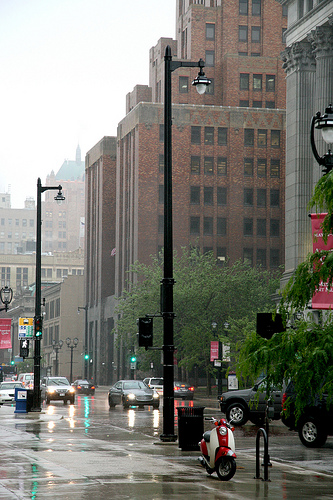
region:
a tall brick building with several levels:
[85, 0, 285, 383]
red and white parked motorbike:
[196, 414, 237, 479]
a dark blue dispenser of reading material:
[13, 386, 26, 414]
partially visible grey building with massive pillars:
[283, 1, 331, 328]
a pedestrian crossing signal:
[19, 337, 30, 357]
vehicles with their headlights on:
[30, 370, 193, 408]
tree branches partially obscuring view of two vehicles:
[217, 304, 331, 446]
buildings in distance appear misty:
[0, 142, 84, 286]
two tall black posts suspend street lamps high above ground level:
[29, 44, 211, 440]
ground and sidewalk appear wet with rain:
[0, 386, 330, 498]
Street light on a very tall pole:
[30, 174, 69, 418]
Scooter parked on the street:
[193, 413, 241, 483]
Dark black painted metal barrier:
[252, 425, 273, 484]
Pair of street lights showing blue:
[81, 352, 140, 365]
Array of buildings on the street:
[0, 0, 332, 405]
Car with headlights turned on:
[105, 375, 161, 409]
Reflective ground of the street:
[0, 393, 331, 498]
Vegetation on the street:
[106, 242, 332, 444]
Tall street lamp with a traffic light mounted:
[136, 42, 212, 448]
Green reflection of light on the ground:
[79, 392, 94, 448]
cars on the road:
[3, 361, 332, 448]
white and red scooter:
[193, 410, 244, 480]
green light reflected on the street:
[79, 394, 94, 435]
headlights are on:
[121, 387, 161, 403]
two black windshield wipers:
[48, 376, 70, 387]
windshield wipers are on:
[49, 377, 70, 386]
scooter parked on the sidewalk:
[191, 411, 246, 480]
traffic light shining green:
[78, 350, 92, 366]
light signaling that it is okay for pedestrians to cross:
[19, 335, 30, 348]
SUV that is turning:
[212, 368, 301, 427]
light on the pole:
[155, 40, 211, 91]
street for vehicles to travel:
[146, 381, 306, 427]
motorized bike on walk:
[187, 408, 234, 470]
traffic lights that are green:
[72, 350, 144, 365]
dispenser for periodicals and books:
[8, 387, 33, 410]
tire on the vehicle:
[292, 414, 332, 448]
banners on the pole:
[205, 339, 233, 362]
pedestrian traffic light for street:
[19, 338, 31, 359]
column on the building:
[276, 41, 314, 287]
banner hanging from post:
[291, 200, 332, 329]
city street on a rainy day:
[15, 255, 302, 489]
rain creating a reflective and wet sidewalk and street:
[1, 387, 325, 492]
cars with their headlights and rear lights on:
[34, 372, 193, 403]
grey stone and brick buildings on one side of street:
[0, 0, 324, 388]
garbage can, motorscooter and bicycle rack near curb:
[174, 403, 267, 477]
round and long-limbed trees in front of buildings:
[122, 250, 327, 425]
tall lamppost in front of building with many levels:
[83, 0, 280, 439]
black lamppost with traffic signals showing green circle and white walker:
[16, 175, 40, 410]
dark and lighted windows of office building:
[178, 119, 278, 206]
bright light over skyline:
[0, 3, 173, 209]